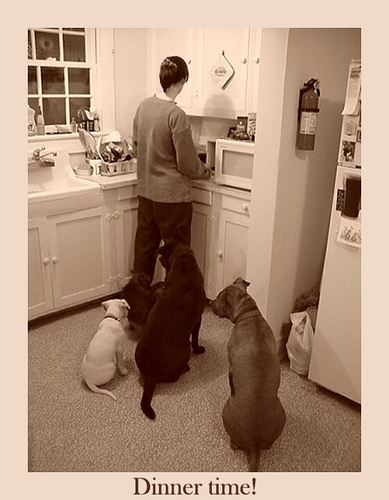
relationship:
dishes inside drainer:
[100, 133, 133, 162] [89, 157, 140, 179]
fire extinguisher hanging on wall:
[296, 78, 320, 151] [245, 28, 360, 347]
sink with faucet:
[28, 151, 101, 212] [29, 145, 59, 169]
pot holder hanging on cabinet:
[207, 51, 236, 89] [200, 30, 246, 121]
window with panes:
[27, 28, 96, 135] [30, 56, 94, 71]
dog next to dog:
[203, 278, 287, 476] [142, 235, 204, 424]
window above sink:
[27, 28, 96, 135] [28, 151, 101, 212]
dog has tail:
[203, 278, 287, 476] [238, 447, 265, 473]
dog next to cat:
[203, 278, 287, 476] [120, 266, 173, 325]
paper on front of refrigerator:
[338, 223, 360, 247] [301, 54, 370, 405]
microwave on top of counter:
[215, 137, 257, 188] [161, 161, 258, 218]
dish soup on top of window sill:
[30, 100, 48, 132] [26, 128, 122, 140]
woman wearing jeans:
[128, 52, 214, 348] [135, 190, 185, 324]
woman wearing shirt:
[128, 52, 214, 348] [128, 96, 201, 205]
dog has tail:
[142, 235, 204, 424] [139, 374, 158, 426]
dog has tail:
[82, 296, 131, 402] [82, 380, 116, 405]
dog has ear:
[203, 278, 287, 476] [233, 279, 251, 289]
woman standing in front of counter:
[128, 52, 214, 348] [161, 161, 258, 218]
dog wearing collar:
[82, 296, 131, 402] [103, 313, 119, 323]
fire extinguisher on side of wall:
[296, 78, 320, 151] [245, 28, 360, 347]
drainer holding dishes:
[89, 157, 140, 179] [100, 133, 133, 162]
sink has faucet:
[28, 151, 101, 212] [29, 145, 59, 169]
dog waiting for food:
[203, 278, 287, 476] [193, 150, 230, 189]